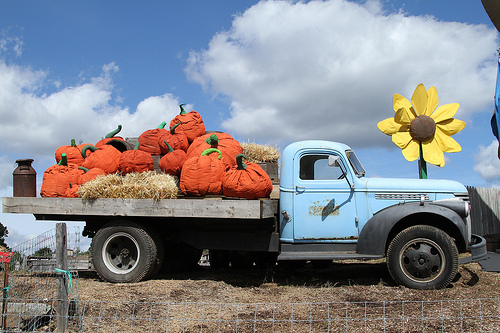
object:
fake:
[168, 110, 206, 143]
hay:
[73, 169, 180, 201]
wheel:
[88, 220, 165, 284]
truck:
[0, 139, 488, 292]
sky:
[0, 0, 500, 82]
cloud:
[273, 1, 496, 76]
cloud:
[5, 20, 193, 112]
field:
[0, 265, 500, 333]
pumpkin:
[159, 122, 190, 154]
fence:
[465, 185, 500, 253]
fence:
[287, 297, 500, 332]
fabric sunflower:
[375, 84, 467, 169]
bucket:
[12, 158, 38, 196]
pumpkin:
[221, 153, 273, 200]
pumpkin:
[176, 139, 240, 192]